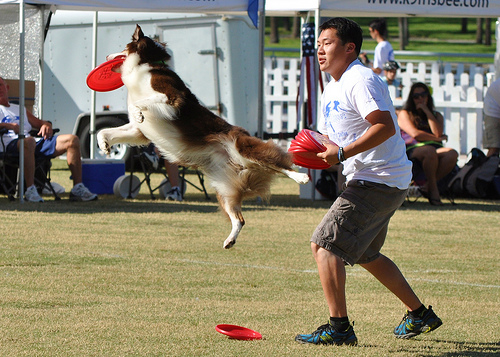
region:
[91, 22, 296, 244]
a dog jumping up in the air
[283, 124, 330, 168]
a pile of frisbees in the man's hand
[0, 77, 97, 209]
a man sitting in the chari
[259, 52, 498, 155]
wooden fences off to the side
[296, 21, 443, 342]
a man playing with a dog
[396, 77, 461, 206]
a woman sitting in a chair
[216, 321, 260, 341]
a frisbee on the ground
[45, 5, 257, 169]
a shed behind the people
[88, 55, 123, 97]
another frisbee in the dogs mouth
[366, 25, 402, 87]
random people standing around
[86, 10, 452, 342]
an Asian man playing frisbee with a large dog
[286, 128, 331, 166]
a stack of red frisbees in the man's hand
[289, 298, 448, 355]
the black and blue athletic shoes the man is wearing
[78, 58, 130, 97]
a red frisbee in the dog's mouth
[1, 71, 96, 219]
a man in a lawn chair watching the dog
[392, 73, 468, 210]
a lady in the background sitting in a lawn chair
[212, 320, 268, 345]
a red frisbee laying on the ground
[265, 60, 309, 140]
several white picket fences in the distance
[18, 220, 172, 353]
green and brown grass they are playing in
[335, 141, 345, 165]
a bracelet on the man's wrist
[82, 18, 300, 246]
dog catching a red frisbee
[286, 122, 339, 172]
stack of red frisbees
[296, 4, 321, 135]
United States flag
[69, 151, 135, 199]
blue and white cooler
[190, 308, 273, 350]
frisbee lying on grass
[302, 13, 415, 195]
man in white t-shirt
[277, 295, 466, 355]
men's sneakers with blue and green trim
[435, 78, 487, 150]
section of white picket fence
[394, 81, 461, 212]
seated woman watching event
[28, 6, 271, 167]
white automotive trailer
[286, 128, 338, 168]
a large stack of red frisbees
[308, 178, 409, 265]
man wearing knee length gray shorts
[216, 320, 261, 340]
red frisbee on the ground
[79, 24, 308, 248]
dog is jumping over a frisbee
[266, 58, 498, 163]
white picket fence behind man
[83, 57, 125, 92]
dog catching frisbee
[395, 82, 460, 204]
woman sitting in front of fence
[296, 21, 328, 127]
america flag windsock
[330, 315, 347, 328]
man wearing short black socks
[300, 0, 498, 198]
woman sitting under canopy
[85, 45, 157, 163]
Red frisbee in dog's mouth.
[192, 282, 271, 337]
Red frisbee on ground.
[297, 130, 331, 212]
Man holding stack of red frisbees.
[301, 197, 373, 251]
Man wearing gray shorts.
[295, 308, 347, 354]
Man wearing blue shoes.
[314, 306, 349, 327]
Man wearing dark socks.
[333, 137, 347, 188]
Band around man's wrist.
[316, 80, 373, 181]
Man wearing white shirt.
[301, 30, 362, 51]
Man has dark hair.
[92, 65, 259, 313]
Dog jumping in air.